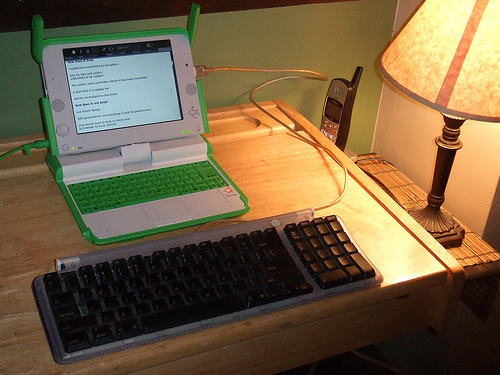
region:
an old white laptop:
[19, 37, 256, 225]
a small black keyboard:
[27, 204, 389, 368]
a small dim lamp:
[377, 0, 494, 250]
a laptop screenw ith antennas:
[23, 7, 240, 149]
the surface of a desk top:
[13, 44, 491, 366]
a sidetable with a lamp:
[352, 0, 499, 317]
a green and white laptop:
[29, 4, 249, 238]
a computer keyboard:
[34, 209, 386, 357]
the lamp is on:
[380, 0, 499, 242]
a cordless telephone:
[326, 64, 359, 150]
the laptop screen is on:
[62, 43, 186, 130]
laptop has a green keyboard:
[66, 160, 229, 212]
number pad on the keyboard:
[286, 215, 376, 290]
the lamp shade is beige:
[382, 0, 499, 125]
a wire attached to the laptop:
[191, 59, 351, 214]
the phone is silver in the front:
[320, 80, 347, 140]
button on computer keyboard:
[288, 226, 302, 241]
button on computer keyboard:
[301, 221, 317, 236]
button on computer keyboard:
[315, 218, 332, 233]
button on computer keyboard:
[327, 217, 344, 231]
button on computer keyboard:
[294, 238, 308, 250]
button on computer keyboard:
[310, 235, 322, 249]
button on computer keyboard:
[319, 232, 336, 245]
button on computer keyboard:
[334, 229, 351, 244]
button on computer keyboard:
[302, 252, 317, 266]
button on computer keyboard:
[313, 247, 330, 259]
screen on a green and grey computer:
[61, 45, 189, 129]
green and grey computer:
[26, 13, 256, 248]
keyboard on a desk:
[18, 203, 386, 365]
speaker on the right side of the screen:
[184, 80, 196, 97]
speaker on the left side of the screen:
[48, 98, 66, 114]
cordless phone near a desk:
[318, 61, 367, 152]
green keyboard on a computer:
[65, 156, 230, 213]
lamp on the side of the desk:
[371, 0, 498, 256]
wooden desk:
[1, 94, 468, 374]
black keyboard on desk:
[62, 231, 323, 328]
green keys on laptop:
[97, 151, 202, 246]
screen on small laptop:
[81, 44, 191, 132]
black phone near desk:
[317, 65, 367, 169]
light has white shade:
[387, 5, 488, 103]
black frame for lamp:
[411, 124, 493, 262]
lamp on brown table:
[372, 144, 494, 284]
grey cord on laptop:
[261, 90, 365, 225]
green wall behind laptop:
[227, 18, 267, 90]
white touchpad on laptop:
[135, 191, 210, 242]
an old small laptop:
[30, 30, 250, 245]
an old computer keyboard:
[23, 200, 397, 361]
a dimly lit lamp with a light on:
[376, 3, 491, 260]